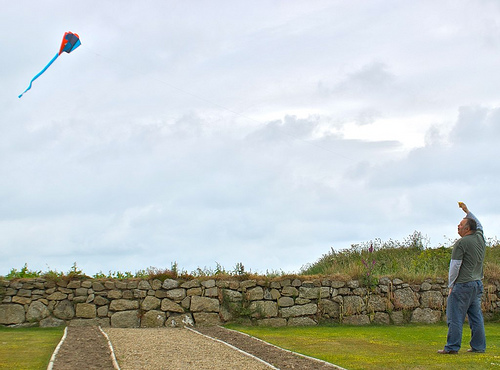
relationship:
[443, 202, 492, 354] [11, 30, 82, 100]
man looking at kite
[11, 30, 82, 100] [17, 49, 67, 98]
kite has tail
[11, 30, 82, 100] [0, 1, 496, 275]
kite flying in air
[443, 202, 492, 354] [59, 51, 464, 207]
man holding onto string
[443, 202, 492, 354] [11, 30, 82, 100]
man flying kite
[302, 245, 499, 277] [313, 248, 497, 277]
mound has grass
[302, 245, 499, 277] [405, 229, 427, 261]
mound has weeds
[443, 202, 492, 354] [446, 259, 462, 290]
man wearing shirt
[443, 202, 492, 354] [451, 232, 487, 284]
man wearing shirt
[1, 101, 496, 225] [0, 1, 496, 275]
cloud cover in air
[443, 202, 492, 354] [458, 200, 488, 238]
man raising arm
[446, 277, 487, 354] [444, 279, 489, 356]
jeans on legs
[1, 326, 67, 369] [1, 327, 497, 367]
grass growing on ground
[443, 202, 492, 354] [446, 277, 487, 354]
man has jeans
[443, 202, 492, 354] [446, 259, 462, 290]
man has shirt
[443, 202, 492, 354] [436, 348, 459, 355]
man has shoe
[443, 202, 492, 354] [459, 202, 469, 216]
man has hand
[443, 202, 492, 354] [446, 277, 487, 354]
man wearing jeans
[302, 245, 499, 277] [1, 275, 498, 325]
mound sitting on top of wall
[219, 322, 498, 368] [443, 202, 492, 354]
grass grows near man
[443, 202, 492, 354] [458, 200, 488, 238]
man holding arm